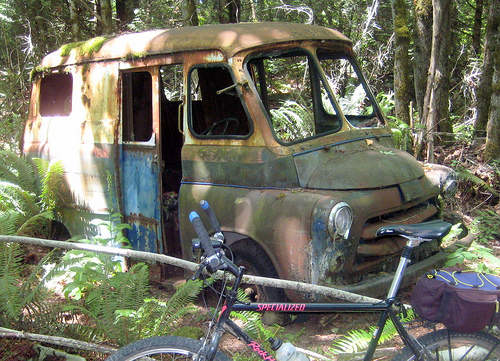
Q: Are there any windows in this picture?
A: Yes, there is a window.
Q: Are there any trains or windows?
A: Yes, there is a window.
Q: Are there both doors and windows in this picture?
A: Yes, there are both a window and a door.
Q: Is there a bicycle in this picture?
A: Yes, there is a bicycle.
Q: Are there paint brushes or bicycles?
A: Yes, there is a bicycle.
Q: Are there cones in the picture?
A: No, there are no cones.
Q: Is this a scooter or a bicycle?
A: This is a bicycle.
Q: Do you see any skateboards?
A: No, there are no skateboards.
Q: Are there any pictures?
A: No, there are no pictures.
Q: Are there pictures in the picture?
A: No, there are no pictures.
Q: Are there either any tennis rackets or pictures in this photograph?
A: No, there are no pictures or tennis rackets.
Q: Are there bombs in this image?
A: No, there are no bombs.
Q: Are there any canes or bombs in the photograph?
A: No, there are no bombs or canes.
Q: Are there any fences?
A: Yes, there is a fence.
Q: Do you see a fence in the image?
A: Yes, there is a fence.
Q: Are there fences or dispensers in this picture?
A: Yes, there is a fence.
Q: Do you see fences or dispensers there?
A: Yes, there is a fence.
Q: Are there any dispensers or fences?
A: Yes, there is a fence.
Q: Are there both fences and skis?
A: No, there is a fence but no skis.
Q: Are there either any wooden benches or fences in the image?
A: Yes, there is a wood fence.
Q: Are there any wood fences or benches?
A: Yes, there is a wood fence.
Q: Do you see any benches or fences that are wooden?
A: Yes, the fence is wooden.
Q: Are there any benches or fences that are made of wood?
A: Yes, the fence is made of wood.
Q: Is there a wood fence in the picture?
A: Yes, there is a wood fence.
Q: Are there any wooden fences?
A: Yes, there is a wood fence.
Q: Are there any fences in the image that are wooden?
A: Yes, there is a fence that is wooden.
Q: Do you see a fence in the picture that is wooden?
A: Yes, there is a fence that is wooden.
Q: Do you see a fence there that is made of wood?
A: Yes, there is a fence that is made of wood.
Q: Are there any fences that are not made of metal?
A: Yes, there is a fence that is made of wood.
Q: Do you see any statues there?
A: No, there are no statues.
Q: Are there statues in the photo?
A: No, there are no statues.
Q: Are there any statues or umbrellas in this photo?
A: No, there are no statues or umbrellas.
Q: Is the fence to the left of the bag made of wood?
A: Yes, the fence is made of wood.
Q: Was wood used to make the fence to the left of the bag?
A: Yes, the fence is made of wood.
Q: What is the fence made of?
A: The fence is made of wood.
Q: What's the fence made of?
A: The fence is made of wood.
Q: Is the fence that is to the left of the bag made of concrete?
A: No, the fence is made of wood.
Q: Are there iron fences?
A: No, there is a fence but it is made of wood.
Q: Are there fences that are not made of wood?
A: No, there is a fence but it is made of wood.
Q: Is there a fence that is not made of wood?
A: No, there is a fence but it is made of wood.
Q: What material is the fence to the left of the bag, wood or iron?
A: The fence is made of wood.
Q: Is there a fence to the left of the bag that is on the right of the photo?
A: Yes, there is a fence to the left of the bag.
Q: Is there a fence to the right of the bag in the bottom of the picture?
A: No, the fence is to the left of the bag.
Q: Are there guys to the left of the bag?
A: No, there is a fence to the left of the bag.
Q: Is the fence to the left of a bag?
A: Yes, the fence is to the left of a bag.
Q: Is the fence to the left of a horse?
A: No, the fence is to the left of a bag.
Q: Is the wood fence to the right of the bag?
A: No, the fence is to the left of the bag.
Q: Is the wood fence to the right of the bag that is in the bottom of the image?
A: No, the fence is to the left of the bag.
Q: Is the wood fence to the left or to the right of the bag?
A: The fence is to the left of the bag.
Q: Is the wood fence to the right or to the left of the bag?
A: The fence is to the left of the bag.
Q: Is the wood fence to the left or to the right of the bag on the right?
A: The fence is to the left of the bag.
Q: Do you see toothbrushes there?
A: No, there are no toothbrushes.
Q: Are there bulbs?
A: No, there are no bulbs.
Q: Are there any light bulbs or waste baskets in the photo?
A: No, there are no light bulbs or waste baskets.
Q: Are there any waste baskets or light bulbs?
A: No, there are no light bulbs or waste baskets.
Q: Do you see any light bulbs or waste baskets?
A: No, there are no light bulbs or waste baskets.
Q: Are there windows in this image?
A: Yes, there is a window.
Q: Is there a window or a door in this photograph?
A: Yes, there is a window.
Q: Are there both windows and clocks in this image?
A: No, there is a window but no clocks.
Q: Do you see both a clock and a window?
A: No, there is a window but no clocks.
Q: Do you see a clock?
A: No, there are no clocks.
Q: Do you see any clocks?
A: No, there are no clocks.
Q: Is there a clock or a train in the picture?
A: No, there are no clocks or trains.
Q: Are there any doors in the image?
A: Yes, there is a door.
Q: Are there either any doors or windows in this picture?
A: Yes, there is a door.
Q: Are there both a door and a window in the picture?
A: Yes, there are both a door and a window.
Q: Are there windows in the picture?
A: Yes, there is a window.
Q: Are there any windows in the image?
A: Yes, there is a window.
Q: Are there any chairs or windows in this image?
A: Yes, there is a window.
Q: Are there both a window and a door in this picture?
A: Yes, there are both a window and a door.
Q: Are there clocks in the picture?
A: No, there are no clocks.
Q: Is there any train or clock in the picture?
A: No, there are no clocks or trains.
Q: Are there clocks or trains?
A: No, there are no clocks or trains.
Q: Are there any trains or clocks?
A: No, there are no clocks or trains.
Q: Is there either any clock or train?
A: No, there are no clocks or trains.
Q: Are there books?
A: No, there are no books.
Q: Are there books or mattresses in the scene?
A: No, there are no books or mattresses.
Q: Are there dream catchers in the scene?
A: No, there are no dream catchers.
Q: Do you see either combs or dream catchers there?
A: No, there are no dream catchers or combs.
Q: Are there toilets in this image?
A: No, there are no toilets.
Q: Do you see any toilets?
A: No, there are no toilets.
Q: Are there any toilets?
A: No, there are no toilets.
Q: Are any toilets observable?
A: No, there are no toilets.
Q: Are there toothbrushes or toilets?
A: No, there are no toilets or toothbrushes.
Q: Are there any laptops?
A: No, there are no laptops.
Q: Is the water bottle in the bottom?
A: Yes, the water bottle is in the bottom of the image.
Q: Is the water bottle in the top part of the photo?
A: No, the water bottle is in the bottom of the image.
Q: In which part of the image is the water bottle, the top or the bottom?
A: The water bottle is in the bottom of the image.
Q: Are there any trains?
A: No, there are no trains.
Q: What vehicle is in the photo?
A: The vehicle is a car.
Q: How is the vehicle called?
A: The vehicle is a car.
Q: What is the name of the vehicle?
A: The vehicle is a car.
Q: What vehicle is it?
A: The vehicle is a car.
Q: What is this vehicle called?
A: This is a car.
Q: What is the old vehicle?
A: The vehicle is a car.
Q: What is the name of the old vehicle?
A: The vehicle is a car.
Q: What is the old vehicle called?
A: The vehicle is a car.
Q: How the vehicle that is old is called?
A: The vehicle is a car.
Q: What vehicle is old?
A: The vehicle is a car.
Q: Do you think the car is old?
A: Yes, the car is old.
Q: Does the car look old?
A: Yes, the car is old.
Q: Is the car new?
A: No, the car is old.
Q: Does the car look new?
A: No, the car is old.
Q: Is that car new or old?
A: The car is old.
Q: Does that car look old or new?
A: The car is old.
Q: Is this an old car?
A: Yes, this is an old car.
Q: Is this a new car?
A: No, this is an old car.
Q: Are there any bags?
A: Yes, there is a bag.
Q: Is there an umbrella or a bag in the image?
A: Yes, there is a bag.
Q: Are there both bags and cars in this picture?
A: Yes, there are both a bag and a car.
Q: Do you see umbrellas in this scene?
A: No, there are no umbrellas.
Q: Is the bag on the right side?
A: Yes, the bag is on the right of the image.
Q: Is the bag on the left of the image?
A: No, the bag is on the right of the image.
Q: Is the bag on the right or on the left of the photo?
A: The bag is on the right of the image.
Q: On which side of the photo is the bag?
A: The bag is on the right of the image.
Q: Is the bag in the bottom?
A: Yes, the bag is in the bottom of the image.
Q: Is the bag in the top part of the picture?
A: No, the bag is in the bottom of the image.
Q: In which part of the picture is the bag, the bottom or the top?
A: The bag is in the bottom of the image.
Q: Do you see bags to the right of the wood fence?
A: Yes, there is a bag to the right of the fence.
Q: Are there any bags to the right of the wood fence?
A: Yes, there is a bag to the right of the fence.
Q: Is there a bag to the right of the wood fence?
A: Yes, there is a bag to the right of the fence.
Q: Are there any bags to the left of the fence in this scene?
A: No, the bag is to the right of the fence.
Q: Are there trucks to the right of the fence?
A: No, there is a bag to the right of the fence.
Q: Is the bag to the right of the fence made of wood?
A: Yes, the bag is to the right of the fence.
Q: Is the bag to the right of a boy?
A: No, the bag is to the right of the fence.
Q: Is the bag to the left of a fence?
A: No, the bag is to the right of a fence.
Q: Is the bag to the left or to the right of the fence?
A: The bag is to the right of the fence.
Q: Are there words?
A: Yes, there are words.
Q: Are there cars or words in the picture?
A: Yes, there are words.